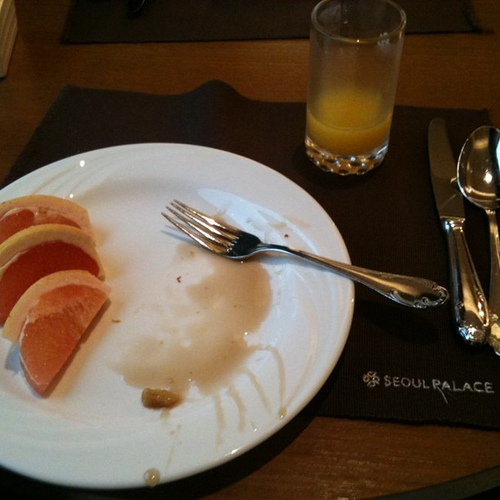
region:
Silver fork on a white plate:
[163, 195, 450, 319]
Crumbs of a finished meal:
[131, 376, 189, 412]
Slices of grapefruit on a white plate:
[8, 189, 117, 396]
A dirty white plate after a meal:
[5, 129, 372, 493]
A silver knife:
[418, 115, 491, 349]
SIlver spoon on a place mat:
[453, 119, 497, 252]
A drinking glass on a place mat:
[298, 4, 405, 175]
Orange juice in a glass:
[298, 86, 401, 158]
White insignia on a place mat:
[356, 362, 495, 402]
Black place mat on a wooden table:
[18, 73, 498, 437]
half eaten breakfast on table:
[9, 13, 488, 388]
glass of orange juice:
[288, 6, 427, 181]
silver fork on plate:
[133, 191, 445, 326]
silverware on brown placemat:
[424, 107, 499, 379]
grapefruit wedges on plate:
[3, 183, 100, 410]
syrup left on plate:
[118, 232, 284, 416]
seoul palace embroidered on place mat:
[351, 357, 496, 411]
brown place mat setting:
[33, 78, 493, 438]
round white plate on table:
[8, 152, 364, 479]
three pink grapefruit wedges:
[6, 183, 111, 410]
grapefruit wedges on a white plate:
[10, 202, 113, 351]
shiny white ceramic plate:
[61, 158, 324, 454]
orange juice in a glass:
[310, 2, 395, 174]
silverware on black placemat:
[428, 118, 498, 259]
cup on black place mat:
[305, 15, 402, 184]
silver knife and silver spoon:
[434, 105, 498, 317]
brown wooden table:
[52, 41, 264, 103]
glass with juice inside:
[300, 8, 414, 183]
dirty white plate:
[140, 272, 258, 367]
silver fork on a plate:
[156, 197, 450, 328]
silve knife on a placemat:
[420, 107, 483, 359]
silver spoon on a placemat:
[455, 119, 498, 357]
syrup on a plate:
[199, 274, 263, 333]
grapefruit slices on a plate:
[7, 183, 112, 409]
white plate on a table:
[18, 421, 126, 488]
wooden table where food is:
[308, 425, 439, 475]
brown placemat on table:
[55, 74, 287, 143]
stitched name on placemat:
[359, 361, 498, 415]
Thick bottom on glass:
[279, 100, 405, 188]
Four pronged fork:
[152, 189, 273, 263]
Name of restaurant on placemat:
[355, 341, 499, 436]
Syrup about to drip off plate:
[121, 463, 183, 496]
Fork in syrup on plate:
[122, 176, 367, 419]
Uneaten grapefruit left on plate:
[3, 174, 135, 442]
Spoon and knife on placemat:
[412, 108, 499, 373]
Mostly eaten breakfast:
[8, 11, 480, 471]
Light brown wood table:
[276, 437, 492, 495]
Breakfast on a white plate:
[10, 131, 390, 489]